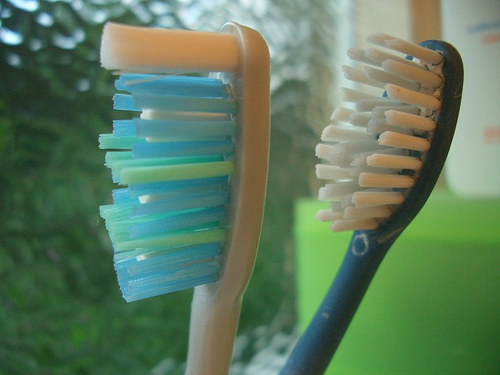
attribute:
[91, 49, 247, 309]
toothbrush — green, white, blue, dark, scum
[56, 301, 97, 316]
grass — green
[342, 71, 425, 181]
bristle — white, blue, green, new, large, different, long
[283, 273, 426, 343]
handle — blue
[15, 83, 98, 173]
bush — green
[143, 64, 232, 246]
bristle — blue, green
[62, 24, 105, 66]
leave — green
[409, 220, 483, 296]
plastic — green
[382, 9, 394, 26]
wall — brown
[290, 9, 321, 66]
window — bathroom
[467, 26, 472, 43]
board — white